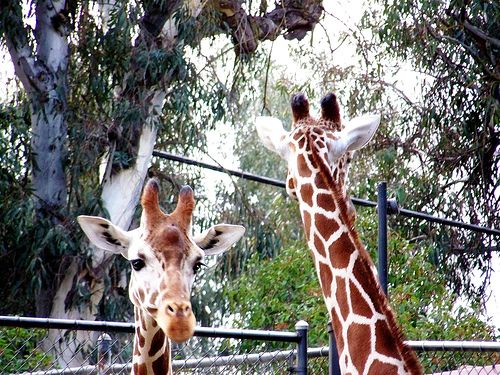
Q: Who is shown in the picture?
A: Giraffes.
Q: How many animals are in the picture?
A: Two.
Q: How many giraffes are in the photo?
A: Two.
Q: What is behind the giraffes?
A: Trees.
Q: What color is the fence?
A: Gray.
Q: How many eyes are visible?
A: Two.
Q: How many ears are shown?
A: Four.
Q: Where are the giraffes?
A: At a zoo.